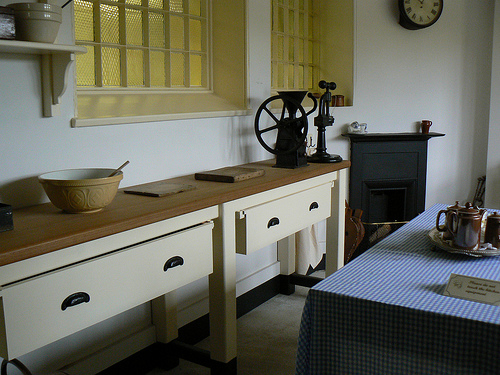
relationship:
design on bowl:
[42, 186, 118, 204] [37, 167, 122, 214]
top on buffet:
[0, 156, 350, 266] [4, 159, 368, 367]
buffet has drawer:
[4, 159, 368, 367] [234, 183, 334, 257]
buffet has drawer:
[4, 159, 368, 367] [4, 218, 212, 359]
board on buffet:
[195, 167, 265, 181] [4, 159, 368, 367]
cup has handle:
[422, 121, 431, 135] [428, 120, 431, 125]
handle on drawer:
[265, 216, 280, 228] [234, 183, 334, 257]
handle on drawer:
[308, 202, 319, 211] [234, 183, 334, 257]